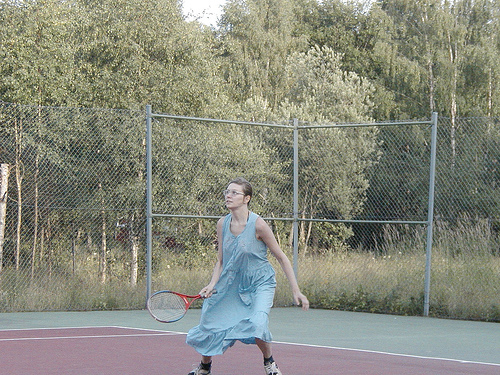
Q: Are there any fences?
A: Yes, there is a fence.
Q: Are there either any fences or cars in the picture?
A: Yes, there is a fence.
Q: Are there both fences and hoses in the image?
A: No, there is a fence but no hoses.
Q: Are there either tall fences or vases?
A: Yes, there is a tall fence.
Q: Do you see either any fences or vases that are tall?
A: Yes, the fence is tall.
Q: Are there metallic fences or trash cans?
A: Yes, there is a metal fence.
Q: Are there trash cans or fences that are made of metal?
A: Yes, the fence is made of metal.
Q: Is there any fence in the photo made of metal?
A: Yes, there is a fence that is made of metal.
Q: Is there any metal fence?
A: Yes, there is a fence that is made of metal.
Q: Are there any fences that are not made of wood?
A: Yes, there is a fence that is made of metal.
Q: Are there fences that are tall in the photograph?
A: Yes, there is a tall fence.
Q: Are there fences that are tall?
A: Yes, there is a fence that is tall.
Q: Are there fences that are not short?
A: Yes, there is a tall fence.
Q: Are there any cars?
A: No, there are no cars.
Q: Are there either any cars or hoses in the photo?
A: No, there are no cars or hoses.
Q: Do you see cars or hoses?
A: No, there are no cars or hoses.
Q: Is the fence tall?
A: Yes, the fence is tall.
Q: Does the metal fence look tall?
A: Yes, the fence is tall.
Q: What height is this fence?
A: The fence is tall.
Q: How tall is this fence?
A: The fence is tall.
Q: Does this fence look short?
A: No, the fence is tall.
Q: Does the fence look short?
A: No, the fence is tall.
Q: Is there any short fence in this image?
A: No, there is a fence but it is tall.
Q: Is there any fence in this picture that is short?
A: No, there is a fence but it is tall.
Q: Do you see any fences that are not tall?
A: No, there is a fence but it is tall.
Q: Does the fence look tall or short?
A: The fence is tall.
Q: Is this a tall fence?
A: Yes, this is a tall fence.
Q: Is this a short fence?
A: No, this is a tall fence.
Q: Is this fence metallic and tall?
A: Yes, the fence is metallic and tall.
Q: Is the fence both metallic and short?
A: No, the fence is metallic but tall.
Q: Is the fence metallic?
A: Yes, the fence is metallic.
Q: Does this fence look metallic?
A: Yes, the fence is metallic.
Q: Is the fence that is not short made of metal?
A: Yes, the fence is made of metal.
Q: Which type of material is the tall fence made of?
A: The fence is made of metal.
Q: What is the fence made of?
A: The fence is made of metal.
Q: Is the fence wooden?
A: No, the fence is metallic.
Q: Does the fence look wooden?
A: No, the fence is metallic.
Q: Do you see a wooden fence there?
A: No, there is a fence but it is metallic.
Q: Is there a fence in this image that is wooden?
A: No, there is a fence but it is metallic.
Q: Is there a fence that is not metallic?
A: No, there is a fence but it is metallic.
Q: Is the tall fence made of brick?
A: No, the fence is made of metal.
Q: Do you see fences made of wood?
A: No, there is a fence but it is made of metal.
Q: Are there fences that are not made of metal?
A: No, there is a fence but it is made of metal.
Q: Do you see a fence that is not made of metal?
A: No, there is a fence but it is made of metal.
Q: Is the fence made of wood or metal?
A: The fence is made of metal.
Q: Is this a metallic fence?
A: Yes, this is a metallic fence.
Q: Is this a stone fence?
A: No, this is a metallic fence.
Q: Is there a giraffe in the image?
A: No, there are no giraffes.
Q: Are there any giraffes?
A: No, there are no giraffes.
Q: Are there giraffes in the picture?
A: No, there are no giraffes.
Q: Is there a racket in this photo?
A: Yes, there is a racket.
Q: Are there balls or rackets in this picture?
A: Yes, there is a racket.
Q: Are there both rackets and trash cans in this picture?
A: No, there is a racket but no trash cans.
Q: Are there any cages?
A: No, there are no cages.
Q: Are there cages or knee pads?
A: No, there are no cages or knee pads.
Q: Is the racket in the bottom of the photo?
A: Yes, the racket is in the bottom of the image.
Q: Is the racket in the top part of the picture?
A: No, the racket is in the bottom of the image.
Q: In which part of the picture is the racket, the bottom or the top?
A: The racket is in the bottom of the image.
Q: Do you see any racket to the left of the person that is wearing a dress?
A: Yes, there is a racket to the left of the person.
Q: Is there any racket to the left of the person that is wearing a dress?
A: Yes, there is a racket to the left of the person.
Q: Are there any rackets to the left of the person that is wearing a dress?
A: Yes, there is a racket to the left of the person.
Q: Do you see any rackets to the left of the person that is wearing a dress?
A: Yes, there is a racket to the left of the person.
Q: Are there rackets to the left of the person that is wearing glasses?
A: Yes, there is a racket to the left of the person.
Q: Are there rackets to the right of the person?
A: No, the racket is to the left of the person.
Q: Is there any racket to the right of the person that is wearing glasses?
A: No, the racket is to the left of the person.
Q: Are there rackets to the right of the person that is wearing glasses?
A: No, the racket is to the left of the person.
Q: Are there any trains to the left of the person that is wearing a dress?
A: No, there is a racket to the left of the person.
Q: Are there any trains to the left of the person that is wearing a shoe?
A: No, there is a racket to the left of the person.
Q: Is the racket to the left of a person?
A: Yes, the racket is to the left of a person.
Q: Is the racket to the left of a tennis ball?
A: No, the racket is to the left of a person.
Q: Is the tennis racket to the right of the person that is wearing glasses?
A: No, the tennis racket is to the left of the person.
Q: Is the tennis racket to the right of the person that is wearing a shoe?
A: No, the tennis racket is to the left of the person.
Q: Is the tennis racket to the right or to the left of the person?
A: The tennis racket is to the left of the person.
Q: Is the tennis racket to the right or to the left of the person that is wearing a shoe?
A: The tennis racket is to the left of the person.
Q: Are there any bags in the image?
A: No, there are no bags.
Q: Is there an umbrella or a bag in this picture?
A: No, there are no bags or umbrellas.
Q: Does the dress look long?
A: Yes, the dress is long.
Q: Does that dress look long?
A: Yes, the dress is long.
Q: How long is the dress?
A: The dress is long.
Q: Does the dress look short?
A: No, the dress is long.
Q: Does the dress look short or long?
A: The dress is long.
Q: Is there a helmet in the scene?
A: No, there are no helmets.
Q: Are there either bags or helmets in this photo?
A: No, there are no helmets or bags.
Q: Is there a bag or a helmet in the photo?
A: No, there are no helmets or bags.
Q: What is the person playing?
A: The person is playing tennis.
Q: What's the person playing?
A: The person is playing tennis.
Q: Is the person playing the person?
A: Yes, the person is playing tennis.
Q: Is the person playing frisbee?
A: No, the person is playing tennis.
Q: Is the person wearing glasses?
A: Yes, the person is wearing glasses.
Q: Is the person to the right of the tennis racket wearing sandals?
A: No, the person is wearing glasses.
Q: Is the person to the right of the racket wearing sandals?
A: No, the person is wearing glasses.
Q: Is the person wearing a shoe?
A: Yes, the person is wearing a shoe.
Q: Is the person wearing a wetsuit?
A: No, the person is wearing a shoe.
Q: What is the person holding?
A: The person is holding the racket.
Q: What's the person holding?
A: The person is holding the racket.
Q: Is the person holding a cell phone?
A: No, the person is holding the racket.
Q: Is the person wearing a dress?
A: Yes, the person is wearing a dress.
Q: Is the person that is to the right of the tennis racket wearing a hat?
A: No, the person is wearing a dress.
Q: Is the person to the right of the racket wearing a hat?
A: No, the person is wearing a dress.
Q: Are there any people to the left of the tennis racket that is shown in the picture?
A: No, the person is to the right of the tennis racket.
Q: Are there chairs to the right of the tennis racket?
A: No, there is a person to the right of the tennis racket.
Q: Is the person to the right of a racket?
A: Yes, the person is to the right of a racket.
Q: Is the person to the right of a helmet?
A: No, the person is to the right of a racket.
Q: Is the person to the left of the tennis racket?
A: No, the person is to the right of the tennis racket.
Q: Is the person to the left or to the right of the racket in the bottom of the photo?
A: The person is to the right of the racket.